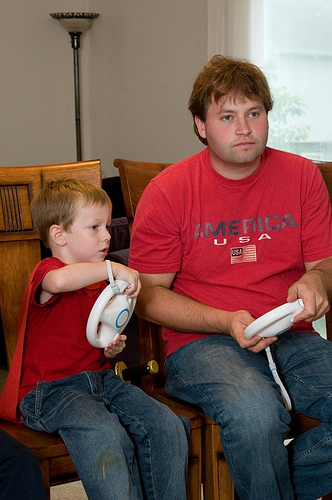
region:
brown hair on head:
[188, 58, 271, 107]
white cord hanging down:
[261, 355, 292, 410]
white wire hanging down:
[256, 348, 303, 412]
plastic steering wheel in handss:
[240, 297, 301, 339]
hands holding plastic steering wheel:
[229, 293, 322, 357]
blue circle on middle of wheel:
[108, 305, 132, 329]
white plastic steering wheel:
[87, 269, 139, 345]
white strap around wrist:
[94, 257, 128, 286]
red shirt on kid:
[21, 262, 112, 383]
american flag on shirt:
[222, 242, 259, 269]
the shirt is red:
[133, 154, 320, 344]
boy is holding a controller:
[27, 172, 146, 374]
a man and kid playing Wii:
[4, 50, 330, 488]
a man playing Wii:
[133, 47, 327, 490]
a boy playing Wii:
[12, 165, 192, 496]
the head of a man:
[179, 49, 284, 180]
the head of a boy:
[23, 175, 121, 267]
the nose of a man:
[235, 123, 253, 136]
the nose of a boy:
[98, 229, 113, 242]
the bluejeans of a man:
[177, 322, 330, 499]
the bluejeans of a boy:
[20, 365, 195, 496]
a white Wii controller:
[82, 264, 144, 353]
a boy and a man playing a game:
[8, 51, 330, 488]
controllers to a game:
[82, 259, 311, 358]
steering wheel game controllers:
[79, 255, 327, 374]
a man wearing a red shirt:
[132, 150, 325, 339]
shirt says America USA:
[186, 215, 297, 244]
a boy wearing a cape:
[2, 251, 119, 423]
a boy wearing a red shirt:
[28, 257, 120, 392]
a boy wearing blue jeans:
[25, 362, 181, 498]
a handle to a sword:
[106, 354, 164, 386]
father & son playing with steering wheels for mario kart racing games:
[80, 276, 327, 365]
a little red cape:
[1, 255, 106, 430]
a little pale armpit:
[25, 278, 59, 310]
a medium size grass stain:
[92, 444, 125, 482]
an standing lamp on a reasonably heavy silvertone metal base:
[46, 4, 103, 162]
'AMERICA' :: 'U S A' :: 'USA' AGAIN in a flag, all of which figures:
[189, 208, 300, 274]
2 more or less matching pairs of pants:
[12, 313, 328, 498]